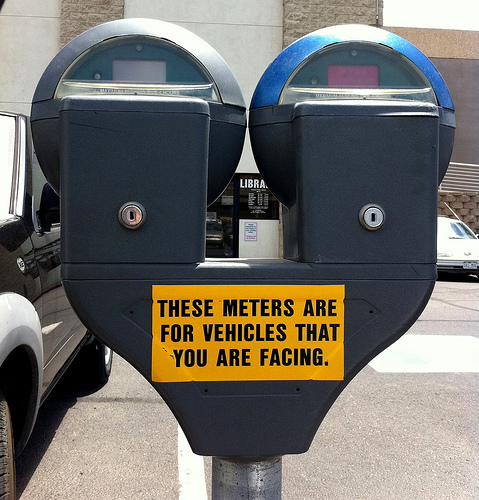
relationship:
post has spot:
[210, 456, 283, 500] [259, 476, 264, 484]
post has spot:
[210, 456, 283, 500] [234, 480, 239, 485]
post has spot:
[210, 456, 283, 500] [217, 460, 223, 470]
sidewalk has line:
[13, 274, 477, 497] [176, 395, 209, 500]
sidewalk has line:
[13, 274, 477, 497] [365, 333, 478, 375]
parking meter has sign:
[30, 17, 458, 462] [152, 284, 345, 382]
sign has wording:
[152, 284, 345, 382] [158, 301, 340, 367]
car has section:
[436, 214, 478, 277] [449, 242, 460, 254]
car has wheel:
[1, 108, 113, 500] [71, 335, 113, 399]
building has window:
[2, 2, 385, 260] [208, 173, 236, 259]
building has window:
[2, 2, 385, 260] [238, 176, 280, 220]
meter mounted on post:
[29, 17, 247, 262] [210, 456, 283, 500]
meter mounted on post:
[250, 23, 457, 261] [210, 456, 283, 500]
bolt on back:
[356, 201, 388, 233] [293, 99, 438, 263]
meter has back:
[29, 17, 247, 262] [60, 95, 207, 264]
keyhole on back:
[128, 210, 136, 220] [60, 95, 207, 264]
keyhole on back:
[369, 212, 377, 222] [293, 99, 438, 263]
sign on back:
[152, 284, 345, 382] [61, 260, 438, 457]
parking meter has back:
[30, 17, 458, 462] [61, 260, 438, 457]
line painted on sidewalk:
[176, 395, 209, 500] [13, 274, 477, 497]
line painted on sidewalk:
[365, 333, 478, 375] [13, 274, 477, 497]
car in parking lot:
[1, 108, 113, 500] [2, 0, 478, 499]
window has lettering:
[238, 176, 280, 220] [241, 177, 268, 214]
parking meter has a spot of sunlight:
[30, 17, 458, 462] [195, 257, 250, 269]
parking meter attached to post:
[30, 17, 458, 462] [210, 456, 283, 500]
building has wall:
[2, 2, 385, 260] [281, 1, 384, 54]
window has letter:
[238, 176, 280, 220] [239, 177, 244, 189]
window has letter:
[238, 176, 280, 220] [247, 177, 253, 188]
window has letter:
[238, 176, 280, 220] [253, 177, 261, 189]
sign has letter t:
[152, 284, 345, 382] [157, 298, 167, 320]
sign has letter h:
[152, 284, 345, 382] [167, 297, 181, 319]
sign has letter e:
[152, 284, 345, 382] [181, 299, 193, 318]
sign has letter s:
[152, 284, 345, 382] [191, 297, 203, 318]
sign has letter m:
[152, 284, 345, 382] [223, 299, 237, 321]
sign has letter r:
[152, 284, 345, 382] [270, 297, 284, 315]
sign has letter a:
[152, 284, 345, 382] [302, 299, 314, 318]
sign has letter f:
[152, 284, 345, 382] [159, 323, 171, 344]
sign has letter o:
[152, 284, 345, 382] [171, 323, 183, 344]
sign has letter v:
[152, 284, 345, 382] [201, 321, 215, 343]